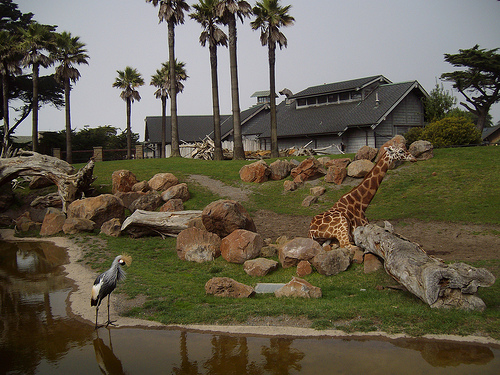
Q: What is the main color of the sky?
A: Blue.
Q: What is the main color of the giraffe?
A: Brown.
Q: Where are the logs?
A: On the ground.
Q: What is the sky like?
A: Overcast.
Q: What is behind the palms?
A: A building.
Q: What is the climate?
A: Tropical.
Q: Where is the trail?
A: On the ground.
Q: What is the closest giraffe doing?
A: Sitting.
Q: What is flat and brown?
A: Water.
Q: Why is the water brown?
A: Dirty.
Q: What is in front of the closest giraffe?
A: A log.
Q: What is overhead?
A: The sky.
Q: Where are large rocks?
A: On the grass.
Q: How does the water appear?
A: Murky.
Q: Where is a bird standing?
A: By the water.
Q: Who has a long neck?
A: A giraffe.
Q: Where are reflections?
A: On the water.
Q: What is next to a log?
A: A giraffe.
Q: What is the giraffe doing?
A: Sitting down.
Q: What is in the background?
A: A building.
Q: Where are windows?
A: On the building.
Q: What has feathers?
A: The bird.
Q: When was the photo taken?
A: Daytime.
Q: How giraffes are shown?
A: One.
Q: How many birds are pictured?
A: One.